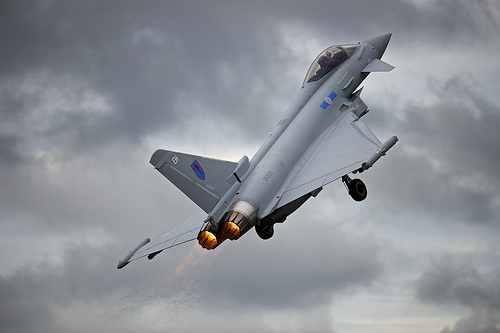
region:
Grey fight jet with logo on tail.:
[112, 30, 402, 271]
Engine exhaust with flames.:
[155, 216, 246, 314]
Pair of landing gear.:
[253, 176, 368, 239]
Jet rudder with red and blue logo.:
[148, 147, 250, 215]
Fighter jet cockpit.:
[301, 41, 362, 87]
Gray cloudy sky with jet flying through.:
[0, 0, 497, 331]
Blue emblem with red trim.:
[188, 158, 206, 182]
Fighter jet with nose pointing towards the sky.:
[113, 33, 400, 270]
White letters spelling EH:
[170, 154, 178, 164]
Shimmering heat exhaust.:
[90, 230, 234, 332]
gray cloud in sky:
[3, 217, 39, 256]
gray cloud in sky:
[44, 139, 76, 167]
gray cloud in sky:
[114, 117, 159, 142]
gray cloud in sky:
[117, 75, 179, 127]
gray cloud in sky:
[28, 37, 81, 81]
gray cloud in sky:
[168, 29, 232, 101]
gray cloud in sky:
[240, 42, 275, 72]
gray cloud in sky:
[321, 241, 375, 293]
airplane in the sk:
[89, 28, 431, 290]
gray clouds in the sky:
[1, 1, 497, 328]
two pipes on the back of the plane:
[185, 210, 253, 266]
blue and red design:
[189, 157, 209, 182]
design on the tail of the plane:
[186, 158, 210, 180]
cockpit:
[290, 39, 358, 85]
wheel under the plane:
[341, 177, 370, 203]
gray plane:
[87, 27, 424, 277]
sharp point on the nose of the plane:
[377, 26, 400, 41]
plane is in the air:
[129, 42, 404, 247]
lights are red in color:
[196, 215, 252, 259]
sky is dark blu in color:
[66, 226, 133, 302]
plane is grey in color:
[171, 68, 392, 201]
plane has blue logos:
[188, 157, 214, 187]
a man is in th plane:
[311, 50, 347, 74]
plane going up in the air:
[178, 37, 387, 244]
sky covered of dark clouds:
[83, 57, 234, 135]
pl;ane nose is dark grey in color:
[353, 12, 400, 65]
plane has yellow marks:
[331, 72, 369, 89]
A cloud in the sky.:
[378, 225, 435, 281]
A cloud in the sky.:
[407, 100, 468, 144]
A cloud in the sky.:
[431, 72, 474, 101]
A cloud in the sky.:
[0, 14, 186, 142]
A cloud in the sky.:
[26, 97, 78, 139]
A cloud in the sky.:
[8, 253, 176, 325]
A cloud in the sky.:
[163, 69, 173, 87]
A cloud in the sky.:
[196, 11, 246, 48]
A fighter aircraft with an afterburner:
[97, 22, 423, 269]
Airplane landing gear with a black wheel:
[332, 168, 373, 200]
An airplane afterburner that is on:
[186, 202, 252, 254]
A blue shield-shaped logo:
[181, 155, 211, 186]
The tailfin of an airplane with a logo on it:
[139, 150, 244, 212]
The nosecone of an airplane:
[362, 21, 394, 57]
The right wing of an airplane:
[262, 97, 401, 247]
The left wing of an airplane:
[119, 211, 210, 272]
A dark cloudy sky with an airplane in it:
[3, 2, 496, 329]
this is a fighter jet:
[78, 0, 485, 300]